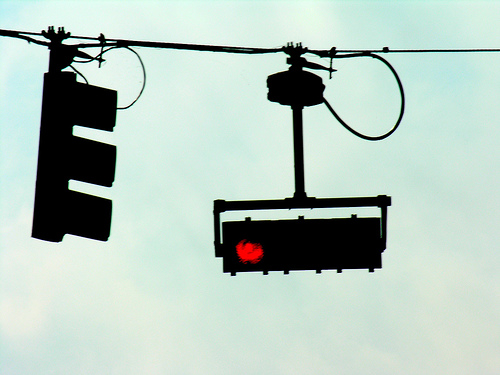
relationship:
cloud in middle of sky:
[1, 213, 150, 335] [1, 0, 500, 373]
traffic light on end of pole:
[221, 216, 384, 275] [291, 104, 309, 198]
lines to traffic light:
[323, 53, 405, 141] [221, 216, 384, 275]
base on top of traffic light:
[212, 196, 392, 214] [221, 216, 384, 275]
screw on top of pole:
[299, 42, 304, 48] [291, 104, 309, 198]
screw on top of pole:
[290, 41, 295, 47] [291, 104, 309, 198]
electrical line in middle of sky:
[0, 28, 499, 53] [1, 0, 500, 373]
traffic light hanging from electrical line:
[221, 216, 384, 275] [0, 28, 499, 53]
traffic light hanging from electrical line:
[32, 72, 120, 242] [0, 28, 499, 53]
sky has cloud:
[1, 0, 500, 373] [1, 213, 150, 335]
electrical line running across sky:
[0, 28, 499, 53] [1, 0, 500, 373]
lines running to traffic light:
[323, 53, 405, 141] [221, 216, 384, 275]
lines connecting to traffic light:
[323, 53, 405, 141] [221, 216, 384, 275]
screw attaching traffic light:
[299, 42, 304, 48] [221, 216, 384, 275]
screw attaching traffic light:
[290, 41, 295, 47] [221, 216, 384, 275]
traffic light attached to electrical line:
[221, 216, 384, 275] [0, 28, 499, 53]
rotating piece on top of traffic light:
[267, 71, 326, 108] [221, 216, 384, 275]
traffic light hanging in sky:
[221, 216, 384, 275] [1, 0, 500, 373]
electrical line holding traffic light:
[0, 28, 499, 53] [221, 216, 384, 275]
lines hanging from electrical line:
[323, 53, 405, 141] [0, 28, 499, 53]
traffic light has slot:
[221, 216, 384, 275] [229, 271, 269, 277]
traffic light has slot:
[221, 216, 384, 275] [283, 270, 321, 276]